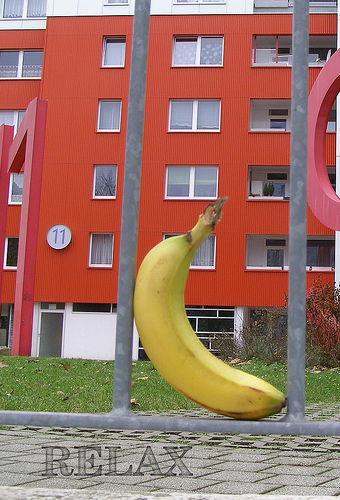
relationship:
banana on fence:
[133, 194, 288, 419] [1, 3, 339, 436]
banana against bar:
[133, 194, 288, 419] [112, 1, 143, 414]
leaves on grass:
[314, 282, 339, 343] [1, 353, 339, 413]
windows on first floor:
[60, 210, 332, 291] [1, 227, 339, 293]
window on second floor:
[7, 169, 22, 206] [1, 157, 339, 208]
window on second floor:
[91, 160, 117, 195] [1, 157, 339, 208]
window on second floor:
[165, 164, 218, 197] [1, 157, 339, 208]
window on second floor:
[264, 182, 284, 197] [1, 157, 339, 208]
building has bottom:
[1, 3, 339, 361] [35, 305, 323, 360]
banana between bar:
[133, 194, 288, 419] [288, 1, 307, 420]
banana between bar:
[133, 194, 288, 419] [112, 1, 150, 414]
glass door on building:
[37, 310, 64, 362] [1, 3, 339, 361]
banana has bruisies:
[133, 194, 288, 419] [242, 385, 266, 403]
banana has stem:
[133, 194, 288, 419] [181, 198, 234, 251]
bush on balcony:
[256, 175, 277, 197] [247, 167, 334, 200]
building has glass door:
[1, 3, 339, 361] [39, 311, 61, 358]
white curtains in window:
[173, 98, 217, 126] [161, 91, 243, 143]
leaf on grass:
[11, 361, 27, 373] [2, 353, 200, 414]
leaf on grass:
[11, 361, 27, 373] [234, 357, 337, 403]